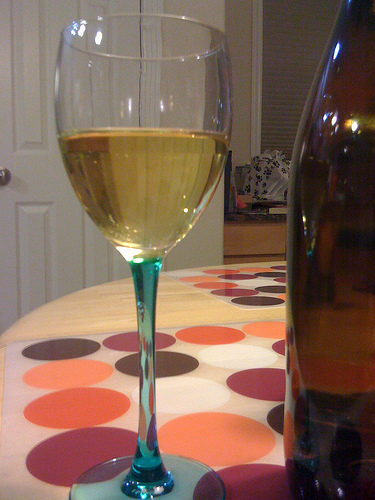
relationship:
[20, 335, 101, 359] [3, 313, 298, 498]
dot on placemat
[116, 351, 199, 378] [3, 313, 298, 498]
dot on placemat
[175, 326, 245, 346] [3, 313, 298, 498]
dot on placemat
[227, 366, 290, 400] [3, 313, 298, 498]
dot on placemat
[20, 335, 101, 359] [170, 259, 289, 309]
dot on placemat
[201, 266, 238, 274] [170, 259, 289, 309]
dot on placemat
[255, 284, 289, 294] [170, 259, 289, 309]
dot on placemat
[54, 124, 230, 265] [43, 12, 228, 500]
wine in glass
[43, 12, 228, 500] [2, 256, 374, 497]
glass on table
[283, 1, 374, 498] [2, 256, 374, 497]
bottle on table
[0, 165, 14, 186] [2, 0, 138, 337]
knob on door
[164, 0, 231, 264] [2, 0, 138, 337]
wall next to door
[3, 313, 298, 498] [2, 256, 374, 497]
placemat on table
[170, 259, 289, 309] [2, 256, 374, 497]
placemat on table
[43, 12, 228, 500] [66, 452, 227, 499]
glass has base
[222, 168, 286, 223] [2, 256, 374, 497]
counter behind table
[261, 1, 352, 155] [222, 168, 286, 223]
shades are behind counter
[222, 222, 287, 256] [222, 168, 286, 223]
drawer under counter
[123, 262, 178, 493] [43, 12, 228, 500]
stem on glass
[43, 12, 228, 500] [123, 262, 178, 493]
glass has stem